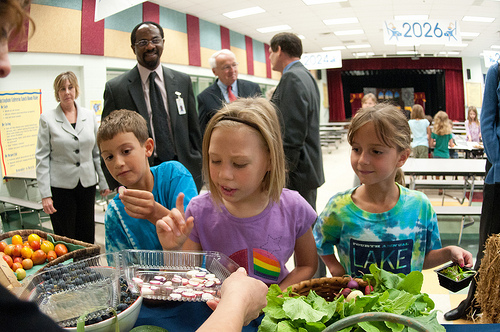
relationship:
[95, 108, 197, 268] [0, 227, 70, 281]
boy are getting free sample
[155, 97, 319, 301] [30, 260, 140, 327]
girl are getting free sample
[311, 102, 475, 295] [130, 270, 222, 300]
girl are getting free radish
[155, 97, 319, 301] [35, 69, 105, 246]
girl are with some woman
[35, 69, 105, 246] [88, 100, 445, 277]
woman are watching children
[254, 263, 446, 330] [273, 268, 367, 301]
greens in a basket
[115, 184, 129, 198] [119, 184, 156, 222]
radish in a hand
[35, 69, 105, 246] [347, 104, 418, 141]
woman with hair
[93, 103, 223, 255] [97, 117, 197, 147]
boy with hair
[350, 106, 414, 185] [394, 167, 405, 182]
hair in ponytail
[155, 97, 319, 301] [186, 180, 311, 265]
girl wearing purple shirt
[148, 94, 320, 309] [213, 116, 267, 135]
girl wearing headband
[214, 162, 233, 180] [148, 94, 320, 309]
nose on girl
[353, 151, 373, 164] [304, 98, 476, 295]
nose on girl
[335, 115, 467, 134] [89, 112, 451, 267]
stage behind children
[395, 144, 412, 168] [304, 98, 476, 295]
ear on girl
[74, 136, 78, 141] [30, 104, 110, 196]
buttons on shirt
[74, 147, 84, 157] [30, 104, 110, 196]
buttons on shirt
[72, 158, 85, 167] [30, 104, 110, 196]
buttons on shirt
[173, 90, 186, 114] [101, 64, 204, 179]
badge on suit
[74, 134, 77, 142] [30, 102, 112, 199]
buttons on jacket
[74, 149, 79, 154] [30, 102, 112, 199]
buttons on jacket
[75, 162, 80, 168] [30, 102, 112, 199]
buttons on jacket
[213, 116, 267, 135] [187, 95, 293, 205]
headband on head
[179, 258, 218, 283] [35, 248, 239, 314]
radish slices in tray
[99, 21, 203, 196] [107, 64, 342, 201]
man in suits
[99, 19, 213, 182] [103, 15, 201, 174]
man wearing glasses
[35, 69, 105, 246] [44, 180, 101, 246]
woman wearing skirt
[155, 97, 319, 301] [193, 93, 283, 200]
girl in her hair